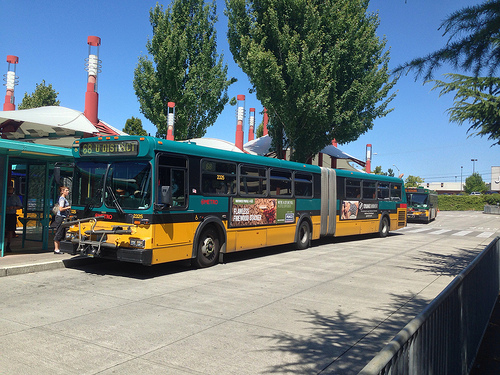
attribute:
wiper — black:
[100, 161, 127, 214]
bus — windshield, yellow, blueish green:
[57, 133, 409, 266]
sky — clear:
[53, 17, 80, 63]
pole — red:
[216, 79, 297, 155]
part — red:
[83, 33, 102, 127]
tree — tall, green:
[118, 1, 236, 133]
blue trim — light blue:
[0, 131, 87, 161]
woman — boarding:
[48, 182, 89, 283]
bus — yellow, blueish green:
[403, 185, 438, 222]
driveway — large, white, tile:
[6, 204, 498, 374]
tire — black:
[192, 217, 222, 268]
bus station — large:
[3, 32, 375, 254]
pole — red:
[85, 35, 98, 125]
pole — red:
[0, 53, 21, 113]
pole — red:
[163, 97, 173, 144]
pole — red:
[233, 91, 243, 153]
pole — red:
[247, 106, 255, 143]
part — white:
[84, 52, 99, 80]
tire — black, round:
[185, 219, 228, 269]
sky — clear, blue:
[0, 0, 499, 183]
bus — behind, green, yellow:
[405, 182, 440, 224]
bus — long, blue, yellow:
[55, 121, 462, 281]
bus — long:
[10, 106, 442, 291]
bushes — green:
[437, 194, 499, 211]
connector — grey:
[319, 165, 336, 239]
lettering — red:
[198, 197, 219, 205]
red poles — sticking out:
[4, 36, 115, 126]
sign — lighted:
[82, 137, 140, 157]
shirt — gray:
[51, 192, 76, 231]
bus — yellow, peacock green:
[56, 129, 410, 281]